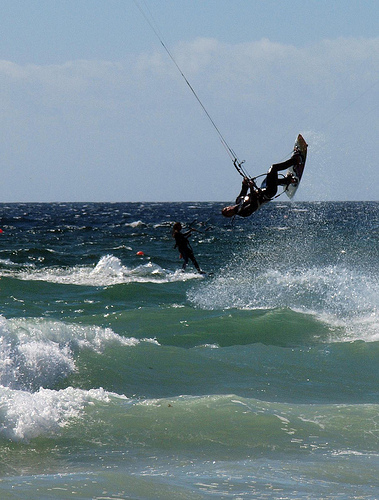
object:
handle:
[185, 219, 212, 233]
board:
[283, 119, 323, 208]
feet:
[284, 141, 299, 189]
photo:
[1, 1, 377, 497]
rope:
[122, 12, 253, 186]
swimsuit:
[233, 158, 296, 219]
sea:
[2, 200, 376, 498]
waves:
[4, 199, 375, 494]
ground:
[256, 138, 268, 167]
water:
[5, 200, 376, 491]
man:
[169, 217, 212, 278]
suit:
[171, 233, 199, 271]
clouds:
[0, 35, 377, 200]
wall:
[137, 145, 157, 167]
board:
[163, 256, 224, 278]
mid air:
[0, 127, 378, 221]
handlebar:
[240, 176, 266, 192]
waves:
[321, 209, 353, 242]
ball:
[134, 245, 146, 258]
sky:
[3, 5, 361, 205]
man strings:
[231, 180, 255, 198]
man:
[217, 132, 308, 222]